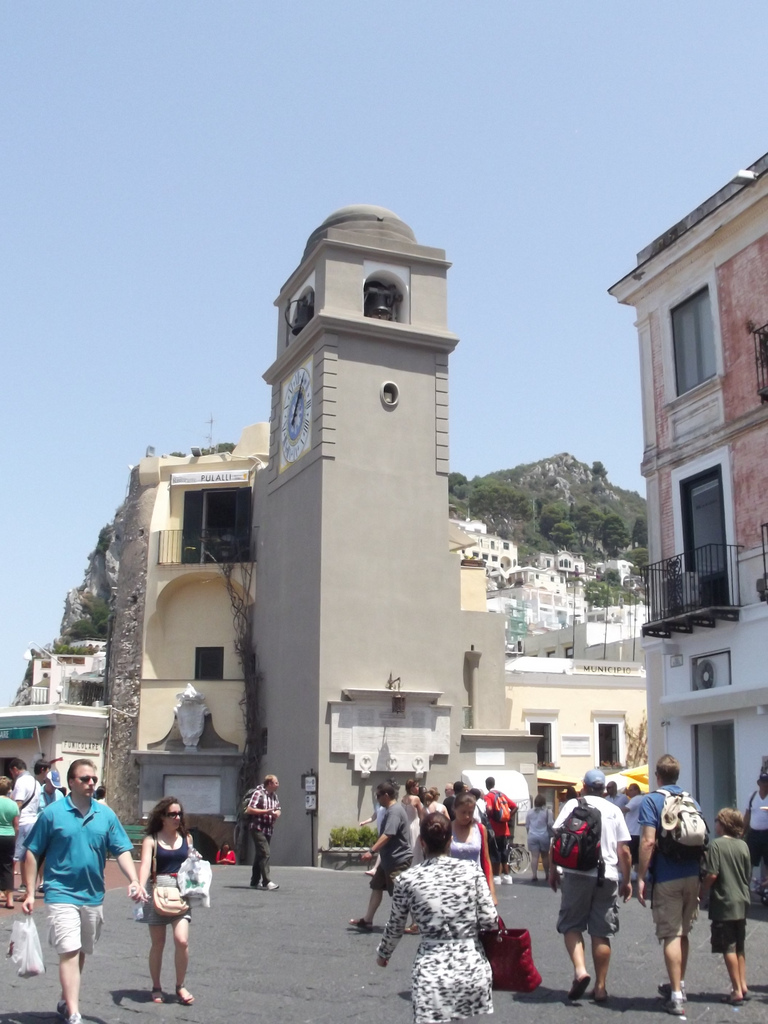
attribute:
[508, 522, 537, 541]
leaves — green 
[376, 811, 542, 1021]
person — walking , walking outside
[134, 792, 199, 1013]
person — walking outside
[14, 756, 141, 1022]
person — walking outside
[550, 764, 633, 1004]
person — walking outside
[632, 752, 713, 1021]
person — walking outside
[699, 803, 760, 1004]
person — walking outside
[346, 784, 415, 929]
person — walking outside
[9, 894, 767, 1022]
ground — grey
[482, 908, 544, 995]
purse — red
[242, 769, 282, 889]
man — bald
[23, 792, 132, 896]
shirt — blue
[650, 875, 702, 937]
shorts — brown